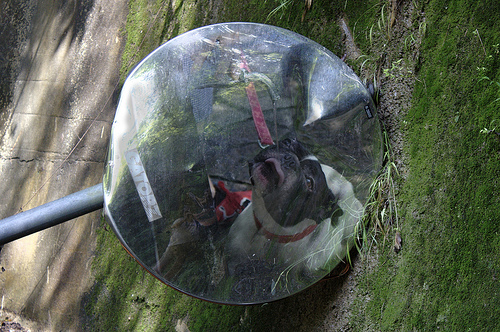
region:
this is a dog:
[196, 128, 350, 243]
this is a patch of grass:
[399, 221, 441, 282]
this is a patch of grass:
[369, 265, 414, 320]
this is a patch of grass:
[414, 187, 464, 276]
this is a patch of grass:
[405, 100, 476, 198]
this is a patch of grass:
[439, 47, 495, 146]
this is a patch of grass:
[431, 180, 496, 286]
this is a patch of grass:
[374, 238, 443, 314]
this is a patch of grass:
[395, 70, 467, 154]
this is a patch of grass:
[436, 126, 487, 208]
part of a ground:
[434, 180, 461, 225]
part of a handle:
[43, 190, 73, 212]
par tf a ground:
[426, 178, 454, 219]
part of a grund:
[407, 227, 432, 262]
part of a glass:
[250, 167, 287, 222]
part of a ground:
[383, 179, 416, 245]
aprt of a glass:
[176, 218, 195, 257]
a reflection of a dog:
[228, 97, 353, 276]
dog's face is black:
[246, 140, 324, 224]